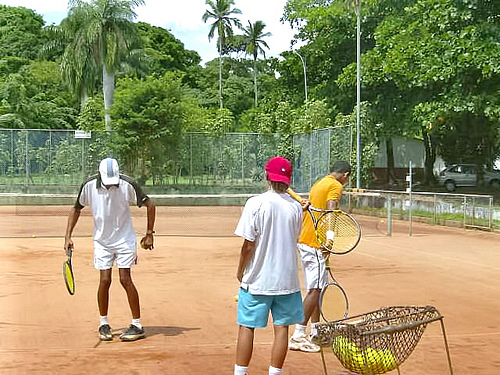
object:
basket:
[310, 299, 448, 373]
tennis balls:
[352, 348, 388, 374]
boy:
[230, 156, 307, 375]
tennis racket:
[285, 187, 362, 256]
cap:
[261, 156, 296, 187]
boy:
[285, 161, 353, 355]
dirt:
[0, 204, 497, 373]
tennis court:
[0, 184, 499, 373]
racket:
[59, 241, 80, 295]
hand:
[63, 236, 76, 255]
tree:
[52, 0, 145, 163]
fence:
[0, 124, 353, 195]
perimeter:
[0, 103, 499, 223]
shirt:
[234, 188, 305, 296]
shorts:
[92, 245, 138, 270]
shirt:
[295, 175, 344, 248]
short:
[296, 244, 329, 292]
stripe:
[107, 158, 113, 178]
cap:
[96, 156, 122, 192]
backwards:
[275, 147, 298, 156]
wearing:
[251, 155, 296, 200]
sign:
[74, 129, 91, 139]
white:
[99, 162, 109, 175]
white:
[110, 213, 125, 230]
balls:
[379, 348, 399, 370]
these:
[308, 305, 439, 375]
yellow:
[351, 352, 376, 364]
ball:
[331, 335, 357, 362]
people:
[234, 157, 306, 375]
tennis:
[375, 346, 402, 370]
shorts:
[237, 288, 307, 329]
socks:
[234, 364, 247, 375]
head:
[263, 156, 292, 181]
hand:
[140, 233, 155, 249]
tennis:
[61, 246, 79, 297]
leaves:
[0, 0, 216, 186]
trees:
[332, 0, 500, 191]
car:
[438, 162, 500, 193]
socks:
[99, 315, 111, 331]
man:
[62, 154, 162, 343]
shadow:
[92, 320, 203, 344]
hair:
[330, 159, 352, 175]